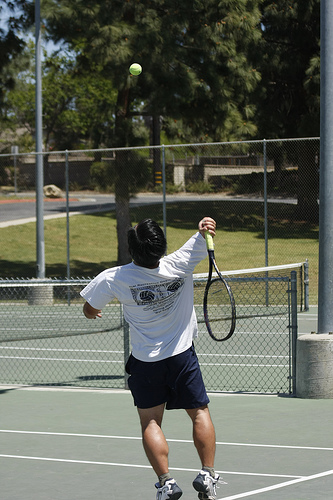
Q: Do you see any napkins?
A: No, there are no napkins.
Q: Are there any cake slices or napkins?
A: No, there are no napkins or cake slices.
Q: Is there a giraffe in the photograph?
A: No, there are no giraffes.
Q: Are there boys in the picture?
A: No, there are no boys.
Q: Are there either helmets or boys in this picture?
A: No, there are no boys or helmets.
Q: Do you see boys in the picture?
A: No, there are no boys.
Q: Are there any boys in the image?
A: No, there are no boys.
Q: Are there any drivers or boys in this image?
A: No, there are no boys or drivers.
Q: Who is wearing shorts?
A: The man is wearing shorts.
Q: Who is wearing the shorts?
A: The man is wearing shorts.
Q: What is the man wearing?
A: The man is wearing shorts.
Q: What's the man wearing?
A: The man is wearing shorts.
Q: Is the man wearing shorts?
A: Yes, the man is wearing shorts.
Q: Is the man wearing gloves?
A: No, the man is wearing shorts.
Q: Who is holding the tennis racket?
A: The man is holding the tennis racket.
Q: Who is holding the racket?
A: The man is holding the tennis racket.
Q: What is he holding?
A: The man is holding the tennis racket.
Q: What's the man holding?
A: The man is holding the tennis racket.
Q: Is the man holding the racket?
A: Yes, the man is holding the racket.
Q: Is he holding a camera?
A: No, the man is holding the racket.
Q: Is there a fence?
A: Yes, there is a fence.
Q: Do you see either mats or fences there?
A: Yes, there is a fence.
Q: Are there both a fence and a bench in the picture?
A: No, there is a fence but no benches.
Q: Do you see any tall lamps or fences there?
A: Yes, there is a tall fence.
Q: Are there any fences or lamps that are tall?
A: Yes, the fence is tall.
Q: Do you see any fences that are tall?
A: Yes, there is a tall fence.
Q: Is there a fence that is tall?
A: Yes, there is a fence that is tall.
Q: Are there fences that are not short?
A: Yes, there is a tall fence.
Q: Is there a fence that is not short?
A: Yes, there is a tall fence.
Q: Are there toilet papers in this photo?
A: No, there are no toilet papers.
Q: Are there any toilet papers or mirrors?
A: No, there are no toilet papers or mirrors.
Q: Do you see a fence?
A: Yes, there is a fence.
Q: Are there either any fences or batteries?
A: Yes, there is a fence.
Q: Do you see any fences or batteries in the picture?
A: Yes, there is a fence.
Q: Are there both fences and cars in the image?
A: No, there is a fence but no cars.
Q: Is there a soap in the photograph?
A: No, there are no soaps.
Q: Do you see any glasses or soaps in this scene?
A: No, there are no soaps or glasses.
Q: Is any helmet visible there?
A: No, there are no helmets.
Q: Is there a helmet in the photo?
A: No, there are no helmets.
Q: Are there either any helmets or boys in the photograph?
A: No, there are no helmets or boys.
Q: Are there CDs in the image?
A: No, there are no cds.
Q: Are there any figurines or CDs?
A: No, there are no CDs or figurines.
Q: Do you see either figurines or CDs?
A: No, there are no CDs or figurines.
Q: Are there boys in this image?
A: No, there are no boys.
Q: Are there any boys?
A: No, there are no boys.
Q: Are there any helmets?
A: No, there are no helmets.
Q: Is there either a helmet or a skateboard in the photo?
A: No, there are no helmets or skateboards.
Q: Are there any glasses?
A: No, there are no glasses.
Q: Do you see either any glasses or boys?
A: No, there are no glasses or boys.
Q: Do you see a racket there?
A: Yes, there is a racket.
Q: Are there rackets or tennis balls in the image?
A: Yes, there is a racket.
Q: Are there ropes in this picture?
A: No, there are no ropes.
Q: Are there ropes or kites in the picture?
A: No, there are no ropes or kites.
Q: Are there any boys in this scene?
A: No, there are no boys.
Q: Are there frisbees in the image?
A: No, there are no frisbees.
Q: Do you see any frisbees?
A: No, there are no frisbees.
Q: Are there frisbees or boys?
A: No, there are no frisbees or boys.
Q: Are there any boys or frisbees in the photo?
A: No, there are no frisbees or boys.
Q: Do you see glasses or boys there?
A: No, there are no boys or glasses.